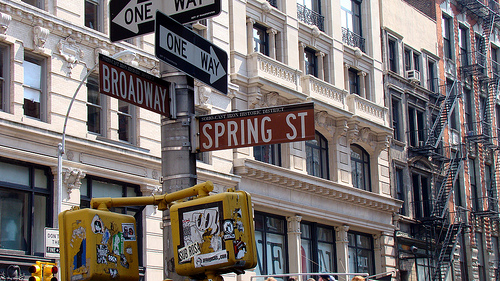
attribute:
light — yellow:
[167, 190, 257, 274]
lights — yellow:
[119, 47, 144, 64]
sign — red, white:
[196, 104, 316, 148]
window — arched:
[351, 143, 371, 187]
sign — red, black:
[179, 103, 339, 158]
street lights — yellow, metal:
[51, 179, 259, 278]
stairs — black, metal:
[418, 1, 495, 276]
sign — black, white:
[154, 10, 229, 95]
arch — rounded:
[350, 141, 371, 164]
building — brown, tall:
[232, 3, 384, 279]